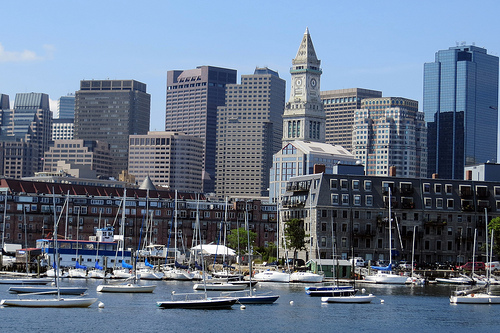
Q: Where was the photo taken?
A: Near water.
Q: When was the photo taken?
A: Day time.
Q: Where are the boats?
A: The water.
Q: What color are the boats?
A: White.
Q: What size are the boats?
A: Small.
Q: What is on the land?
A: Buildings.